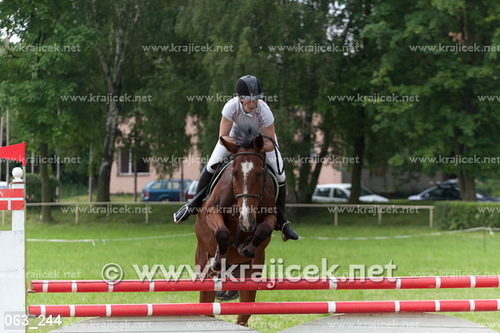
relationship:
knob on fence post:
[11, 166, 23, 181] [1, 166, 31, 331]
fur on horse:
[235, 155, 255, 227] [149, 135, 288, 321]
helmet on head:
[236, 75, 264, 101] [235, 73, 261, 110]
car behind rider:
[313, 183, 391, 203] [172, 73, 299, 240]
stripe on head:
[239, 161, 256, 226] [224, 135, 266, 225]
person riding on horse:
[173, 75, 300, 241] [198, 139, 270, 325]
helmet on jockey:
[230, 73, 261, 99] [199, 79, 284, 181]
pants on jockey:
[209, 142, 287, 208] [176, 75, 298, 239]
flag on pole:
[0, 141, 28, 210] [22, 150, 28, 183]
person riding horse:
[170, 71, 305, 243] [184, 143, 309, 305]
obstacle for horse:
[27, 276, 498, 313] [192, 152, 291, 315]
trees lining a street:
[1, 1, 498, 226] [3, 193, 499, 221]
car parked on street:
[144, 173, 192, 210] [106, 186, 198, 211]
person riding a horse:
[170, 71, 305, 243] [192, 124, 278, 326]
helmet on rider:
[236, 75, 264, 101] [164, 70, 302, 244]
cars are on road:
[140, 178, 492, 203] [46, 194, 488, 211]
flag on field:
[5, 136, 33, 186] [31, 184, 446, 221]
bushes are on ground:
[432, 190, 499, 228] [3, 197, 493, 328]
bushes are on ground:
[432, 200, 499, 233] [3, 197, 493, 328]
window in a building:
[115, 139, 170, 187] [98, 89, 478, 215]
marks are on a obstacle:
[40, 271, 483, 329] [58, 250, 435, 331]